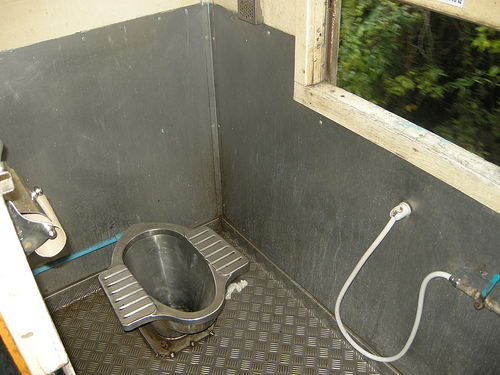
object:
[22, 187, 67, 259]
pipe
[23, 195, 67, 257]
toilet paper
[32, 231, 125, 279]
pipe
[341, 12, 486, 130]
trees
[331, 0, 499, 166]
tree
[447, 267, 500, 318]
pipe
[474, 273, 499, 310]
pipe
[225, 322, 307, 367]
stainless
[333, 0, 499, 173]
leaves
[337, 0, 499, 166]
green leaves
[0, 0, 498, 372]
bathroom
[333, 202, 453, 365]
white hose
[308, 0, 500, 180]
open window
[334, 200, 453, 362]
cord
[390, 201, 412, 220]
cord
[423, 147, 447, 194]
ground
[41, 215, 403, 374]
floor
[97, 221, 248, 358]
toilet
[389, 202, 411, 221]
nozzle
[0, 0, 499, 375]
wall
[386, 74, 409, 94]
leaves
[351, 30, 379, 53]
leaves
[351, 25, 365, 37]
leaf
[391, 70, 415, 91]
leaf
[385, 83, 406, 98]
leaf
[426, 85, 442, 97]
leaf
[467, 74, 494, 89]
leaf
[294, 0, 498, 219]
window frame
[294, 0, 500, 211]
window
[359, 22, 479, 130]
tree